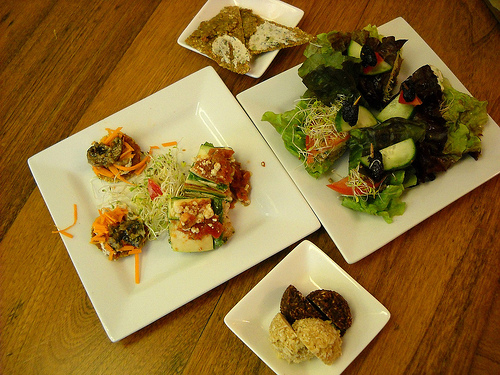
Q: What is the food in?
A: Plates.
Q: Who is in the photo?
A: No one.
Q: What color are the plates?
A: White.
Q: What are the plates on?
A: Table.